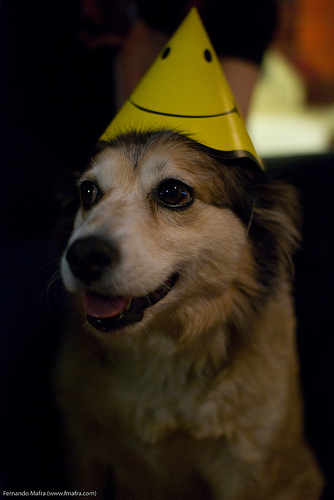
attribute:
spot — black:
[199, 45, 214, 63]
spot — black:
[159, 46, 171, 61]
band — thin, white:
[242, 171, 256, 242]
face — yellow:
[125, 42, 239, 122]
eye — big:
[77, 177, 102, 210]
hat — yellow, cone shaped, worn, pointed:
[92, 0, 263, 170]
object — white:
[218, 46, 321, 158]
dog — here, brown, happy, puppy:
[43, 93, 329, 498]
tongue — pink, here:
[77, 297, 116, 321]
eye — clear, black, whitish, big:
[152, 179, 196, 216]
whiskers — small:
[43, 265, 68, 307]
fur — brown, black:
[199, 161, 260, 349]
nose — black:
[61, 236, 118, 283]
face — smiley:
[123, 31, 231, 121]